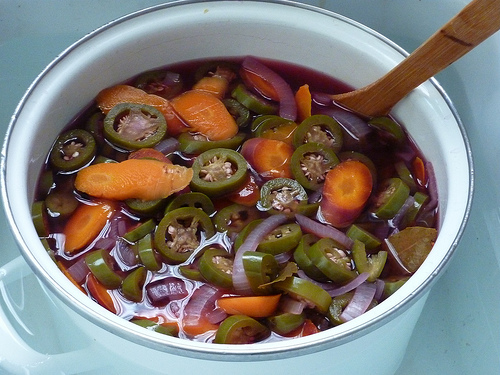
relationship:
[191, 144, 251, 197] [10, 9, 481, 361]
pepper in pot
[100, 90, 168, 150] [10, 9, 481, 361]
pepper in pot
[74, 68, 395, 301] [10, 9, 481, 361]
soup in pot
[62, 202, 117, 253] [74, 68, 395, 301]
carrot in soup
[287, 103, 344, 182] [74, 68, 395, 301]
jalapeno in soup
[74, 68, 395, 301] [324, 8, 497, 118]
soup has spoon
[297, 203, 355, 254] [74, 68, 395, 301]
onions in soup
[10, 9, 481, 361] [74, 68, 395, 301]
pot has soup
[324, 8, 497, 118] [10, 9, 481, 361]
spoon in pot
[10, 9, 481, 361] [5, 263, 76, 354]
pot has handle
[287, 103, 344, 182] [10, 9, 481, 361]
jalapeno in pot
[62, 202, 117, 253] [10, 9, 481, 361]
carrot in pot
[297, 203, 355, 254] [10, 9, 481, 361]
onions in pot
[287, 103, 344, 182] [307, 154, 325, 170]
jalapeno has seeds